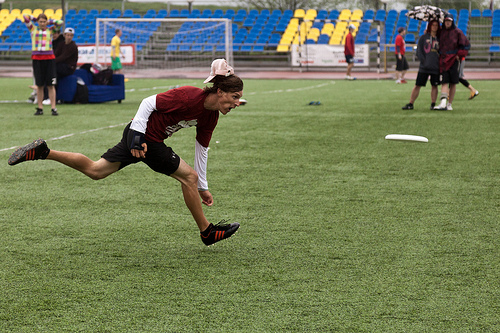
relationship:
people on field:
[13, 10, 481, 255] [2, 72, 500, 332]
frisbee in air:
[383, 127, 430, 148] [322, 58, 465, 182]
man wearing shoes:
[8, 73, 248, 254] [6, 138, 241, 255]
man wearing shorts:
[8, 73, 248, 254] [109, 125, 183, 173]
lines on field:
[4, 87, 494, 164] [2, 72, 500, 332]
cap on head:
[211, 77, 243, 95] [208, 90, 244, 117]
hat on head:
[202, 55, 234, 79] [208, 90, 244, 117]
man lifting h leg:
[8, 73, 248, 254] [17, 135, 137, 181]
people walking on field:
[392, 8, 481, 117] [2, 72, 500, 332]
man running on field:
[8, 73, 248, 254] [2, 72, 500, 332]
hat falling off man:
[202, 55, 234, 79] [8, 73, 248, 254]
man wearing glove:
[8, 73, 248, 254] [124, 127, 145, 147]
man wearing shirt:
[8, 73, 248, 254] [130, 87, 219, 194]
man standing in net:
[103, 20, 129, 72] [103, 24, 222, 75]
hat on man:
[202, 55, 234, 79] [8, 73, 248, 254]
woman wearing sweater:
[20, 17, 74, 116] [25, 20, 59, 57]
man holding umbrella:
[438, 21, 477, 108] [401, 6, 444, 19]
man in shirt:
[103, 20, 129, 72] [106, 34, 122, 57]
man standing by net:
[103, 20, 129, 72] [103, 24, 222, 75]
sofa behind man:
[57, 63, 122, 103] [60, 28, 85, 83]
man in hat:
[60, 28, 85, 83] [62, 26, 71, 35]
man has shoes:
[8, 73, 248, 254] [6, 138, 241, 255]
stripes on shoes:
[25, 148, 224, 242] [6, 138, 241, 255]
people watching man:
[13, 10, 481, 255] [8, 73, 248, 254]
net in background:
[103, 24, 222, 75] [2, 1, 500, 85]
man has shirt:
[8, 73, 248, 254] [130, 87, 219, 194]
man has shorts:
[8, 73, 248, 254] [109, 125, 183, 173]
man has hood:
[412, 16, 440, 113] [427, 17, 437, 34]